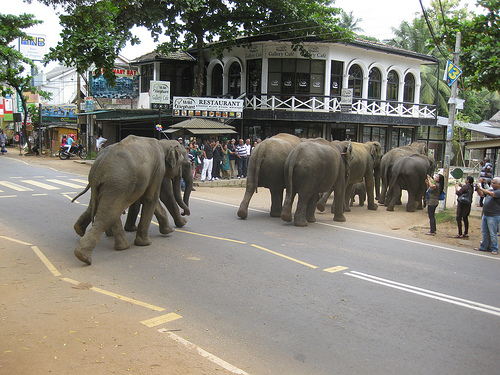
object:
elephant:
[75, 134, 193, 266]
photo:
[1, 2, 499, 374]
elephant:
[280, 137, 353, 224]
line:
[251, 242, 317, 271]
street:
[1, 155, 499, 374]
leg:
[134, 177, 157, 247]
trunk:
[172, 177, 189, 217]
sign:
[172, 97, 245, 118]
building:
[173, 24, 440, 157]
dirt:
[403, 206, 500, 254]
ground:
[0, 188, 499, 316]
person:
[424, 173, 446, 235]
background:
[1, 0, 499, 189]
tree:
[41, 2, 355, 101]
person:
[475, 179, 499, 256]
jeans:
[480, 215, 500, 251]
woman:
[61, 133, 71, 156]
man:
[200, 139, 215, 181]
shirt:
[205, 146, 214, 159]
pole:
[76, 70, 82, 156]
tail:
[71, 181, 91, 203]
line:
[324, 265, 350, 274]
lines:
[345, 270, 499, 318]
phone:
[426, 171, 429, 176]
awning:
[95, 111, 243, 119]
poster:
[87, 65, 140, 97]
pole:
[86, 65, 91, 161]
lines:
[419, 0, 449, 60]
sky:
[331, 0, 433, 43]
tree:
[0, 13, 52, 156]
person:
[236, 140, 249, 181]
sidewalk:
[193, 178, 246, 189]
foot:
[73, 245, 94, 264]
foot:
[136, 234, 150, 246]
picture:
[425, 170, 430, 176]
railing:
[217, 94, 438, 123]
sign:
[444, 63, 461, 87]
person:
[68, 134, 80, 154]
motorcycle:
[60, 143, 89, 160]